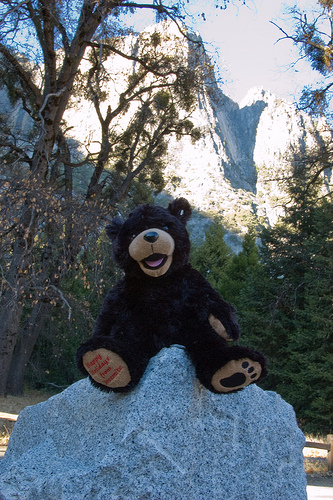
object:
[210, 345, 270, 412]
paw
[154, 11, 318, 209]
mountains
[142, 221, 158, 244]
nose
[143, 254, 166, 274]
tongue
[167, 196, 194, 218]
ear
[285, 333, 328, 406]
leaf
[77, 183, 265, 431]
bear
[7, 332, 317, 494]
rock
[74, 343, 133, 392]
sole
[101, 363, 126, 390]
word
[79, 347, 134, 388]
bottom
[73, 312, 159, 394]
leg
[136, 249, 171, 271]
mouth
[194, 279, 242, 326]
arm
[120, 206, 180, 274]
face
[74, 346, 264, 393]
paws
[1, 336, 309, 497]
boulder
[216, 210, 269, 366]
tree